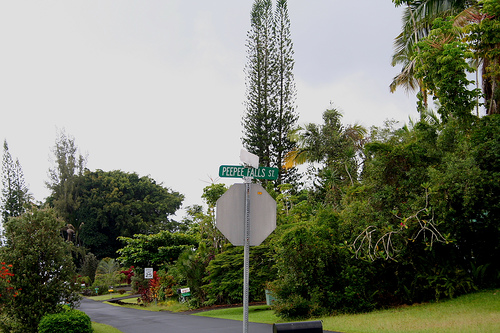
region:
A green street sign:
[215, 154, 286, 186]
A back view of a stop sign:
[207, 178, 288, 330]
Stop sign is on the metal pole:
[239, 185, 256, 325]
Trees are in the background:
[55, 2, 499, 290]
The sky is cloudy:
[1, 3, 438, 178]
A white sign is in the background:
[140, 257, 158, 304]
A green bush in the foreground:
[29, 306, 107, 331]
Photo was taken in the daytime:
[3, 8, 496, 327]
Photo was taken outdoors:
[2, 6, 499, 326]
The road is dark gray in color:
[51, 288, 301, 329]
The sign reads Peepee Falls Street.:
[198, 157, 294, 189]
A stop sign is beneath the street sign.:
[191, 175, 292, 255]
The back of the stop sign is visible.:
[198, 177, 290, 257]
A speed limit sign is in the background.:
[130, 261, 161, 286]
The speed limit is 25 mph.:
[132, 260, 163, 285]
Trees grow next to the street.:
[220, 1, 495, 312]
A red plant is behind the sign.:
[130, 262, 169, 304]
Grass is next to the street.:
[322, 289, 497, 331]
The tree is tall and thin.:
[231, 0, 298, 190]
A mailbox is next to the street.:
[166, 277, 201, 308]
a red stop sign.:
[199, 153, 295, 330]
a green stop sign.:
[210, 151, 292, 188]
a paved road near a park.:
[46, 284, 300, 331]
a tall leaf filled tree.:
[268, 0, 299, 211]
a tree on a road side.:
[260, 212, 332, 332]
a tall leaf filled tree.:
[31, 151, 199, 282]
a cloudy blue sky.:
[0, 0, 497, 249]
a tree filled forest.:
[78, 0, 498, 305]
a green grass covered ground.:
[88, 291, 496, 329]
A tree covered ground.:
[0, 146, 130, 332]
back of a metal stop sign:
[206, 174, 281, 265]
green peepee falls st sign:
[211, 148, 296, 198]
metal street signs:
[209, 142, 305, 316]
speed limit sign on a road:
[130, 258, 168, 309]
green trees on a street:
[305, 98, 459, 308]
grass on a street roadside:
[331, 292, 474, 329]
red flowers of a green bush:
[1, 250, 33, 318]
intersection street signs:
[194, 116, 292, 198]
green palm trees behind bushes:
[389, 0, 498, 183]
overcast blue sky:
[59, 10, 206, 153]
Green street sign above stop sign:
[207, 154, 290, 184]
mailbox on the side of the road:
[176, 285, 196, 311]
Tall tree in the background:
[240, 0, 298, 168]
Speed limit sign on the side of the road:
[137, 266, 157, 308]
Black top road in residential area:
[99, 302, 167, 331]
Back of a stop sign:
[214, 181, 281, 251]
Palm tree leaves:
[391, 0, 464, 33]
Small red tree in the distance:
[119, 262, 138, 287]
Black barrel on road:
[267, 319, 327, 331]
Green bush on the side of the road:
[39, 309, 94, 331]